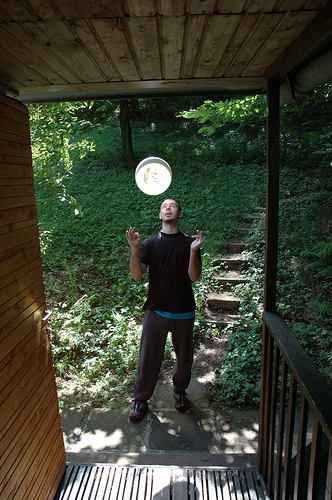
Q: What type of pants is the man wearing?
A: Sweat pants.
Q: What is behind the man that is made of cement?
A: Steps.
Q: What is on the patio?
A: Concrete slab patio outside.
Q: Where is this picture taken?
A: A wooded area outside.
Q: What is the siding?
A: Light pine wood siding on house.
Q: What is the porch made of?
A: Covered porch made of wood.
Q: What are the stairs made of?
A: Wooden slates in dirt for natural stairs.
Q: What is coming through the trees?
A: Sun.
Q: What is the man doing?
A: Man trying to catch freebie as it comes down.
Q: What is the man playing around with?
A: A frisbee.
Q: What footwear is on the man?
A: Sneakers.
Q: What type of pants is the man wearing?
A: Sweatpants.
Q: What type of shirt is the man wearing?
A: A black t-shirt.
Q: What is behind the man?
A: Stairs.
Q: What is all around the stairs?
A: Plants.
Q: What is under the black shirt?
A: A green shirt.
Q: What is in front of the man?
A: Patio steps.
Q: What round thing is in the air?
A: A frisbee.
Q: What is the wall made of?
A: Wood.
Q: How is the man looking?
A: Up.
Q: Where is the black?
A: Shirt.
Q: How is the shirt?
A: Black.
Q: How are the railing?
A: Wood.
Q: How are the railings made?
A: Wood.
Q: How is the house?
A: Wood.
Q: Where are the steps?
A: Behind man.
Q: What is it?
A: Frisbee.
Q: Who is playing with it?
A: The guy.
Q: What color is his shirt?
A: Black.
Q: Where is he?
A: Woods.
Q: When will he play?
A: Soon.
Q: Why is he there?
A: To play.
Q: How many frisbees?
A: 1.